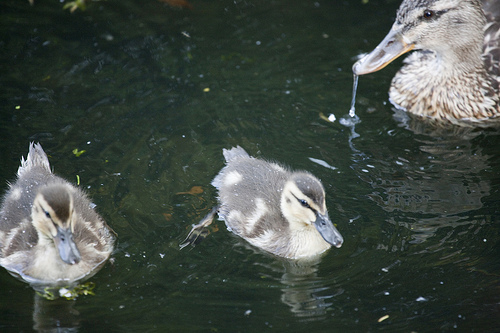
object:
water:
[0, 4, 498, 331]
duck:
[211, 146, 347, 262]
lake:
[0, 1, 499, 333]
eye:
[300, 200, 309, 207]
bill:
[312, 213, 346, 249]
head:
[279, 172, 343, 249]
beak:
[352, 36, 410, 75]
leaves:
[62, 1, 90, 11]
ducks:
[0, 141, 116, 286]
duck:
[353, 1, 500, 129]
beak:
[311, 213, 345, 249]